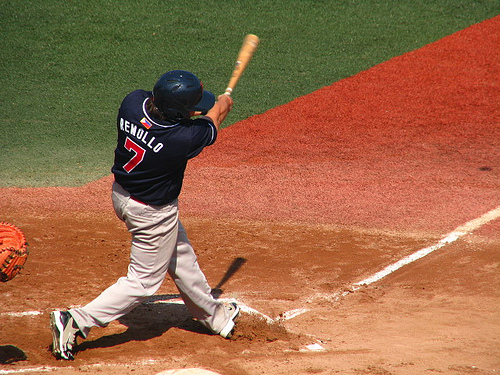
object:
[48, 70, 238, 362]
batter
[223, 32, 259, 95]
bat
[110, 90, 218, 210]
jersey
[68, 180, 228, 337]
pants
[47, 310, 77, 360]
shoe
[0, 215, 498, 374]
sand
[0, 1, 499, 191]
grass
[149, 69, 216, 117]
helmet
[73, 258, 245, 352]
shadow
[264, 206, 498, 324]
line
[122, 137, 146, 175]
number 7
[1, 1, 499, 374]
field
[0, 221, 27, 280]
glove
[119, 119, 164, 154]
name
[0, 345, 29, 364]
shadow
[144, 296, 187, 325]
home plate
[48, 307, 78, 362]
right foot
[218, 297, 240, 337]
left foot